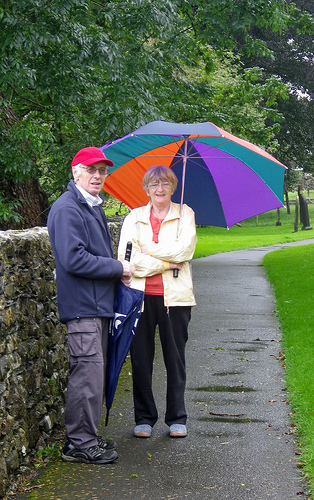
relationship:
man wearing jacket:
[75, 163, 110, 462] [45, 181, 126, 326]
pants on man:
[65, 318, 106, 450] [46, 145, 129, 463]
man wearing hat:
[40, 143, 135, 471] [69, 133, 118, 173]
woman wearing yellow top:
[90, 161, 211, 277] [154, 211, 201, 258]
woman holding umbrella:
[116, 163, 200, 441] [95, 118, 290, 277]